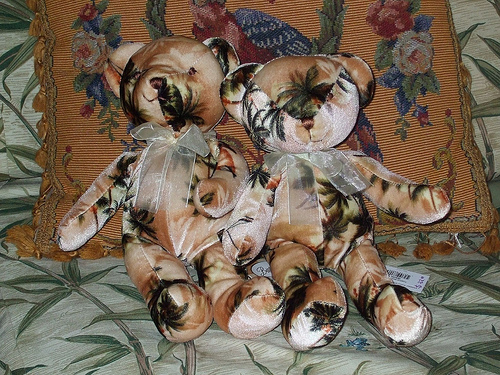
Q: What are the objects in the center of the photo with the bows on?
A: Stuffed animals.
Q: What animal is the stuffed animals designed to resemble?
A: Bear.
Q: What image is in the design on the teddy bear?
A: Palm trees.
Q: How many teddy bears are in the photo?
A: Two.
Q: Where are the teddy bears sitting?
A: Bed.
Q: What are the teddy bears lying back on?
A: Pillow.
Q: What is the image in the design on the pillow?
A: Flowers.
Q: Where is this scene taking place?
A: On a couch.